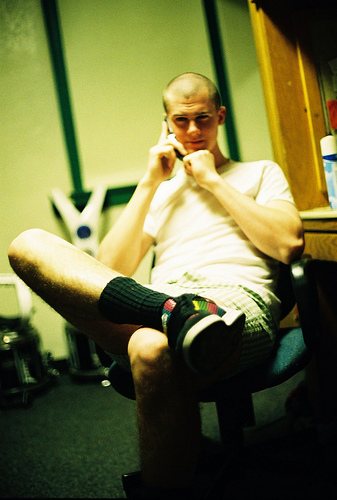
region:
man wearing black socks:
[64, 254, 178, 356]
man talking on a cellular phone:
[13, 41, 316, 474]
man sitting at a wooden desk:
[113, 0, 335, 302]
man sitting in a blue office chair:
[91, 63, 325, 418]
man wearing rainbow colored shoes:
[16, 70, 312, 492]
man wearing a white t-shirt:
[49, 53, 310, 312]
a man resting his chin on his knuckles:
[114, 66, 260, 231]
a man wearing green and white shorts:
[14, 66, 316, 491]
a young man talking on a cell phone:
[4, 69, 313, 498]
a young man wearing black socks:
[13, 64, 312, 497]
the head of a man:
[160, 71, 230, 160]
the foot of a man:
[166, 289, 252, 377]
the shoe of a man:
[160, 287, 251, 377]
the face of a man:
[168, 100, 218, 151]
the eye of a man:
[172, 114, 190, 125]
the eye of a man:
[197, 112, 209, 120]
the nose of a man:
[182, 125, 203, 136]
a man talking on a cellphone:
[133, 69, 235, 191]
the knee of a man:
[129, 330, 167, 359]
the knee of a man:
[6, 225, 40, 261]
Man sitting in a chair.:
[1, 2, 310, 441]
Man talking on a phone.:
[3, 66, 312, 474]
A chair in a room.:
[100, 247, 329, 492]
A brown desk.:
[246, 2, 335, 367]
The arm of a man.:
[179, 144, 304, 268]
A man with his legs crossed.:
[6, 67, 306, 495]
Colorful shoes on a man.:
[160, 286, 247, 370]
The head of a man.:
[160, 70, 230, 153]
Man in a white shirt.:
[4, 66, 306, 397]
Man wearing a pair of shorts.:
[8, 69, 311, 498]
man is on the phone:
[127, 80, 230, 218]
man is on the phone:
[112, 47, 293, 272]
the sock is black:
[80, 267, 153, 359]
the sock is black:
[85, 252, 194, 368]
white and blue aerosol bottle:
[319, 133, 334, 208]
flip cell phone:
[163, 116, 184, 160]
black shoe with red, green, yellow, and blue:
[158, 291, 243, 362]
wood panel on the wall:
[248, 2, 327, 208]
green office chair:
[108, 241, 308, 454]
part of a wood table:
[294, 203, 336, 264]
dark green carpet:
[5, 371, 332, 495]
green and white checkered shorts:
[129, 272, 275, 372]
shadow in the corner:
[256, 1, 332, 79]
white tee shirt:
[142, 155, 291, 295]